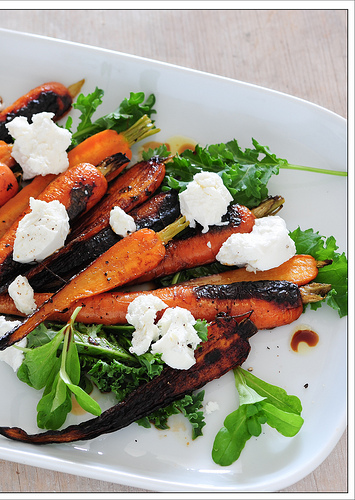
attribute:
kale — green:
[113, 357, 158, 382]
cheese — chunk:
[173, 163, 240, 232]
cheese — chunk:
[6, 107, 78, 183]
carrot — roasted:
[1, 84, 313, 449]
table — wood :
[1, 9, 347, 122]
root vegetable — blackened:
[4, 228, 170, 351]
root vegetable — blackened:
[1, 284, 301, 327]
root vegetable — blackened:
[0, 321, 245, 452]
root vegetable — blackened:
[2, 278, 302, 330]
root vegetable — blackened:
[3, 80, 75, 135]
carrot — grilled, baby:
[0, 157, 108, 270]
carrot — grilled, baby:
[130, 195, 276, 277]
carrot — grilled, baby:
[0, 124, 132, 227]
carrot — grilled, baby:
[0, 82, 78, 149]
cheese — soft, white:
[12, 106, 292, 366]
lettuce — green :
[25, 316, 208, 438]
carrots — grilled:
[0, 215, 182, 359]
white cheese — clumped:
[177, 170, 237, 232]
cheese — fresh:
[151, 305, 200, 372]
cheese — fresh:
[125, 288, 168, 356]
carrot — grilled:
[2, 163, 102, 267]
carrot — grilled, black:
[46, 197, 141, 274]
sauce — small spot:
[289, 328, 320, 348]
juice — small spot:
[290, 327, 318, 351]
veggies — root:
[4, 84, 317, 438]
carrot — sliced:
[168, 252, 331, 290]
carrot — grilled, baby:
[2, 279, 304, 332]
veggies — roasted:
[30, 99, 309, 461]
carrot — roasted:
[119, 190, 285, 284]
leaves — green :
[162, 148, 345, 195]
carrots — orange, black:
[70, 232, 304, 326]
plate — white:
[0, 26, 347, 491]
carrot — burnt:
[4, 80, 317, 371]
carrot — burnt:
[121, 253, 302, 369]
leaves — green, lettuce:
[141, 137, 287, 207]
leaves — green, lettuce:
[289, 225, 346, 316]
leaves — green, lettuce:
[55, 84, 155, 148]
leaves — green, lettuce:
[25, 319, 206, 437]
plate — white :
[5, 86, 334, 412]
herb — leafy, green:
[213, 372, 307, 475]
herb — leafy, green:
[10, 322, 108, 428]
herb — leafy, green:
[291, 225, 351, 321]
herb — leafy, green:
[161, 134, 296, 198]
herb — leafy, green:
[59, 93, 154, 141]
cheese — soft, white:
[223, 216, 302, 275]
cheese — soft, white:
[110, 286, 205, 371]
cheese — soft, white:
[167, 161, 237, 239]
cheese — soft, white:
[3, 188, 75, 267]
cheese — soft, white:
[2, 109, 73, 188]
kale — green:
[63, 339, 208, 439]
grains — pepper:
[100, 258, 121, 321]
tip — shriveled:
[2, 424, 60, 449]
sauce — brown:
[293, 328, 319, 347]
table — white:
[1, 9, 350, 491]